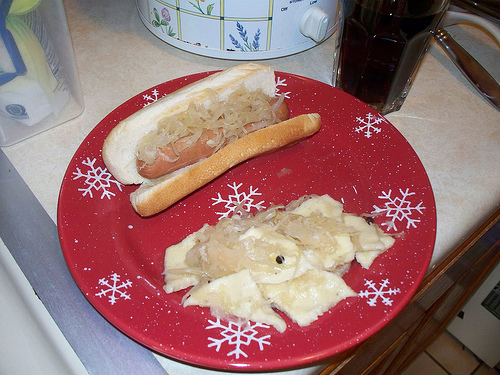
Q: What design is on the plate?
A: Snowflakes.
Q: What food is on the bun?
A: Hot dog.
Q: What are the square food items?
A: Ravioli.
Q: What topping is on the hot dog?
A: Sauerkraut.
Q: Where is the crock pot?
A: Behind the plate.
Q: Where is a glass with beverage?
A: Right side of plate.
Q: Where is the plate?
A: Kitchen counter.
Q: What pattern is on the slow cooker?
A: Flowers.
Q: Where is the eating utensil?
A: Next to glass.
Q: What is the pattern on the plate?
A: Snowflakes.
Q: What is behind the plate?
A: Crockpot.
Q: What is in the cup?
A: A beverage.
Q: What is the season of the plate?
A: Winter.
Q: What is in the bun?
A: A hot dog.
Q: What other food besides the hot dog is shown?
A: Pasta.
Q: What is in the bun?
A: Hot dog.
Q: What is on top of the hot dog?
A: Sauerkraut.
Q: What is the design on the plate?
A: Snowflakes.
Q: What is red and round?
A: The plate.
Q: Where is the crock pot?
A: On the table.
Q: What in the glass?
A: Dark colored beverage.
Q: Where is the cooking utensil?
A: On the table.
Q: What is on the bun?
A: A hotdog.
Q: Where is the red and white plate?
A: On the table.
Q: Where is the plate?
A: On the counter.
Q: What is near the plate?
A: A glass.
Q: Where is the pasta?
A: On the plate.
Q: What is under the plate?
A: Counter.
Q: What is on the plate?
A: Hot dog.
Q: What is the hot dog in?
A: A bun.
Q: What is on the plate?
A: Food.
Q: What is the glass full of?
A: Drink.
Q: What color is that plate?
A: Red.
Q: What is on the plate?
A: A hot dog.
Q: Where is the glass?
A: Beside the plate.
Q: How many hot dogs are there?
A: One.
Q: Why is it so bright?
A: The light is on.